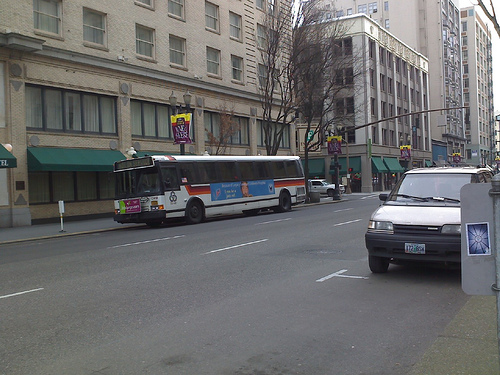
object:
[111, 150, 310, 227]
bus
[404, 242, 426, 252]
license plate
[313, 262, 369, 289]
parking line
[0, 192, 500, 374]
road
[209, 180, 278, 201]
sign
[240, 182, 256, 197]
person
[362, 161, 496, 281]
vehicle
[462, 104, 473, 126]
traffic signal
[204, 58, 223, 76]
window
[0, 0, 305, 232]
buildings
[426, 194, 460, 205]
wiper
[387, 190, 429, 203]
wiper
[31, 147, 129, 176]
awning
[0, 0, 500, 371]
avenue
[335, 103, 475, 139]
pole